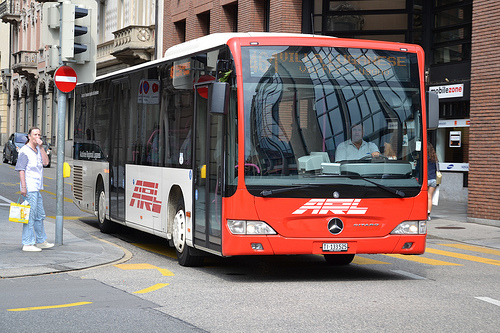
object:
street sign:
[53, 65, 78, 93]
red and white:
[57, 76, 78, 87]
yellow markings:
[128, 280, 168, 294]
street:
[0, 149, 500, 332]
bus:
[71, 31, 428, 267]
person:
[13, 126, 54, 251]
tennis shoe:
[22, 244, 45, 253]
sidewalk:
[0, 195, 125, 279]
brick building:
[0, 0, 500, 228]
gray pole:
[55, 93, 69, 245]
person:
[426, 139, 444, 221]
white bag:
[431, 183, 445, 206]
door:
[195, 84, 222, 251]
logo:
[290, 197, 366, 214]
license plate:
[319, 242, 350, 252]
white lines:
[472, 294, 500, 308]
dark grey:
[97, 312, 161, 331]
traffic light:
[60, 2, 90, 63]